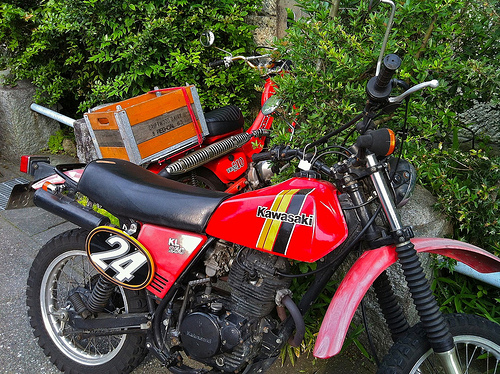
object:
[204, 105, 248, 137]
seat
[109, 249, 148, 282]
number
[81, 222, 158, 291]
logo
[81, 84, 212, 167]
crate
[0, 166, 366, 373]
pavement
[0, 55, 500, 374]
motorcycle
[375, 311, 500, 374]
wheel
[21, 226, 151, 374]
wheel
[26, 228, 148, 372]
tire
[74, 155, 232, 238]
black seat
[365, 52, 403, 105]
rubber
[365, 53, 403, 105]
handle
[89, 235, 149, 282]
24